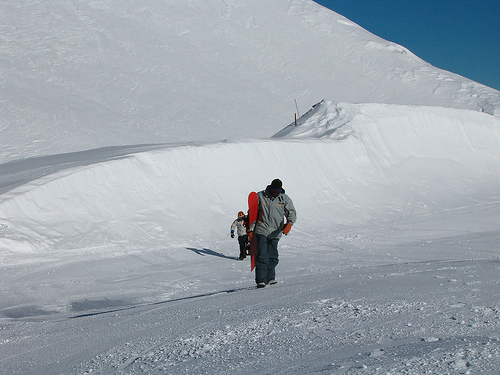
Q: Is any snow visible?
A: Yes, there is snow.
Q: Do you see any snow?
A: Yes, there is snow.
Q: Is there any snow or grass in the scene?
A: Yes, there is snow.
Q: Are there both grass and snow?
A: No, there is snow but no grass.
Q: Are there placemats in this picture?
A: No, there are no placemats.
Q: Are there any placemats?
A: No, there are no placemats.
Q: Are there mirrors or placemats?
A: No, there are no placemats or mirrors.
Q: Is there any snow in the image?
A: Yes, there is snow.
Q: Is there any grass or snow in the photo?
A: Yes, there is snow.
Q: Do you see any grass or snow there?
A: Yes, there is snow.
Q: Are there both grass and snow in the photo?
A: No, there is snow but no grass.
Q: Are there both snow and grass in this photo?
A: No, there is snow but no grass.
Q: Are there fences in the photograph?
A: No, there are no fences.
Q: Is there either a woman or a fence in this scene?
A: No, there are no fences or women.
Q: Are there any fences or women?
A: No, there are no fences or women.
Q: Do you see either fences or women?
A: No, there are no fences or women.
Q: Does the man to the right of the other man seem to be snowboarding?
A: Yes, the man is snowboarding.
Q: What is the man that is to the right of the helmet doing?
A: The man is snowboarding.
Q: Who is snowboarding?
A: The man is snowboarding.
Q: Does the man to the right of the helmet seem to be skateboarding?
A: No, the man is snowboarding.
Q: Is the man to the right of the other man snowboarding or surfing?
A: The man is snowboarding.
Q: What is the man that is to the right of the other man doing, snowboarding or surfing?
A: The man is snowboarding.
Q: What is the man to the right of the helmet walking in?
A: The man is walking in the snow.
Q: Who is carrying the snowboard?
A: The man is carrying the snowboard.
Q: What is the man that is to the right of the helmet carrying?
A: The man is carrying a snowboard.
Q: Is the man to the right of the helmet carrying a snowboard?
A: Yes, the man is carrying a snowboard.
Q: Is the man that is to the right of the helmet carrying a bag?
A: No, the man is carrying a snowboard.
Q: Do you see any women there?
A: No, there are no women.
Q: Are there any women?
A: No, there are no women.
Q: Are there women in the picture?
A: No, there are no women.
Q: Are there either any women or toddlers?
A: No, there are no women or toddlers.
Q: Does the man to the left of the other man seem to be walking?
A: Yes, the man is walking.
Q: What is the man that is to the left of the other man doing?
A: The man is walking.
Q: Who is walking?
A: The man is walking.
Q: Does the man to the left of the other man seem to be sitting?
A: No, the man is walking.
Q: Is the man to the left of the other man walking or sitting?
A: The man is walking.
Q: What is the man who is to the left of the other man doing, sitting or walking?
A: The man is walking.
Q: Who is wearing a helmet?
A: The man is wearing a helmet.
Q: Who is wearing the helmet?
A: The man is wearing a helmet.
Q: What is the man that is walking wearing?
A: The man is wearing a helmet.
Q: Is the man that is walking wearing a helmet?
A: Yes, the man is wearing a helmet.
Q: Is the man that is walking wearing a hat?
A: No, the man is wearing a helmet.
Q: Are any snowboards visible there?
A: Yes, there is a snowboard.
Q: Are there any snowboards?
A: Yes, there is a snowboard.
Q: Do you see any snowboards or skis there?
A: Yes, there is a snowboard.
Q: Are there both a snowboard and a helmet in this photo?
A: Yes, there are both a snowboard and a helmet.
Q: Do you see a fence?
A: No, there are no fences.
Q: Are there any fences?
A: No, there are no fences.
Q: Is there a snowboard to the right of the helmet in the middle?
A: Yes, there is a snowboard to the right of the helmet.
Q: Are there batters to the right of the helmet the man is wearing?
A: No, there is a snowboard to the right of the helmet.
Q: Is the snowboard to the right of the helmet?
A: Yes, the snowboard is to the right of the helmet.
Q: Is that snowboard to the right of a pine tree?
A: No, the snowboard is to the right of the helmet.